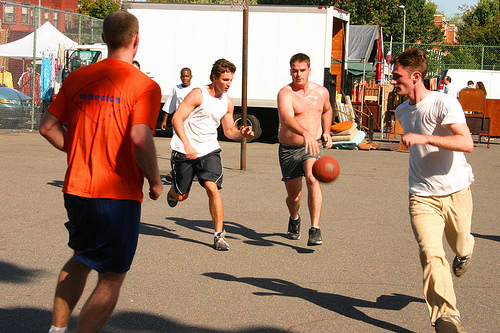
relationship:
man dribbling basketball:
[276, 52, 335, 245] [309, 156, 343, 182]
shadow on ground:
[201, 271, 426, 331] [0, 136, 500, 328]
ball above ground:
[310, 155, 343, 183] [193, 235, 399, 291]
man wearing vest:
[163, 58, 265, 254] [168, 86, 237, 162]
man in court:
[33, 8, 171, 333] [1, 130, 499, 330]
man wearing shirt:
[33, 8, 171, 333] [45, 57, 158, 201]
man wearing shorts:
[275, 52, 336, 251] [275, 137, 320, 179]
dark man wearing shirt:
[161, 66, 203, 182] [170, 82, 199, 127]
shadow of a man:
[201, 271, 426, 331] [390, 51, 474, 331]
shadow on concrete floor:
[201, 271, 426, 331] [0, 127, 500, 333]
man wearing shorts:
[163, 55, 254, 254] [168, 152, 220, 192]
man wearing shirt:
[29, 10, 183, 300] [45, 57, 158, 201]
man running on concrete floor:
[382, 40, 487, 332] [4, 127, 499, 311]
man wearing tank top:
[275, 52, 336, 251] [175, 85, 225, 157]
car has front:
[0, 80, 35, 129] [8, 85, 29, 127]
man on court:
[275, 52, 336, 251] [2, 112, 497, 302]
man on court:
[33, 8, 171, 333] [2, 112, 497, 302]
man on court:
[163, 55, 254, 254] [2, 112, 497, 302]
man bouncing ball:
[275, 52, 336, 251] [307, 155, 338, 182]